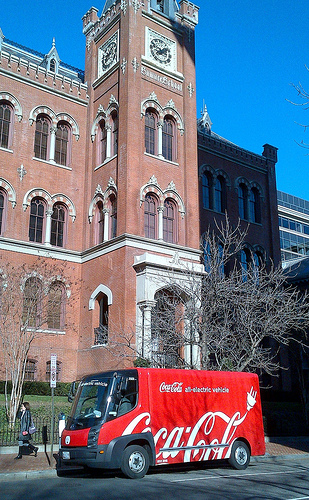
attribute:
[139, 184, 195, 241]
windows — arched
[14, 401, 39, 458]
woman — grey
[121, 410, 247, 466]
letters — big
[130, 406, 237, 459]
lettering — larger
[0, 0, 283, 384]
building — big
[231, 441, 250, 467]
truckwheel — black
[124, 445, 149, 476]
truckwheel — black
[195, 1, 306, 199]
sky — clear, blue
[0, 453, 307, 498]
road — paved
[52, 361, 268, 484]
vehicle — red